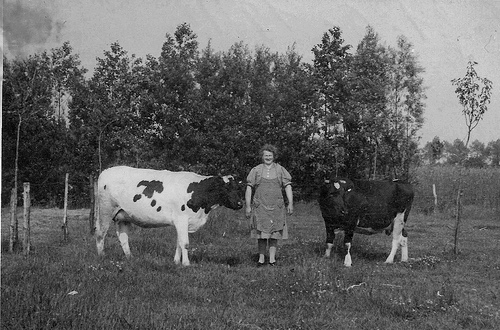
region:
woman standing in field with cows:
[241, 141, 303, 263]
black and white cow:
[87, 163, 242, 270]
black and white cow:
[308, 176, 413, 271]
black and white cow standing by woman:
[323, 176, 415, 268]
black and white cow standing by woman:
[91, 167, 246, 268]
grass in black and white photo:
[14, 261, 252, 328]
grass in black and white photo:
[272, 267, 496, 322]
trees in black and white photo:
[8, 50, 258, 157]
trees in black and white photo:
[200, 40, 414, 141]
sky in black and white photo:
[24, 2, 474, 24]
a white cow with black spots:
[78, 154, 244, 284]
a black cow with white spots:
[301, 176, 439, 273]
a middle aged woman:
[233, 126, 300, 282]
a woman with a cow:
[226, 143, 447, 291]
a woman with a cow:
[81, 133, 283, 269]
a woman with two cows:
[79, 148, 434, 289]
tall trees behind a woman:
[78, 25, 408, 187]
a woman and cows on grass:
[50, 110, 436, 308]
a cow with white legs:
[312, 170, 443, 270]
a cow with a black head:
[123, 160, 248, 321]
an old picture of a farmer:
[10, 6, 487, 321]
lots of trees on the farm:
[8, 15, 487, 235]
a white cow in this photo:
[78, 148, 246, 267]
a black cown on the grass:
[320, 157, 440, 274]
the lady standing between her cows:
[86, 122, 446, 279]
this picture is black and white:
[7, 23, 476, 283]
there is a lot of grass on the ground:
[23, 210, 488, 319]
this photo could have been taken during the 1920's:
[61, 92, 479, 271]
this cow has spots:
[115, 166, 243, 258]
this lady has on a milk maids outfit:
[76, 127, 296, 288]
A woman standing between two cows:
[74, 121, 430, 291]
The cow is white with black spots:
[83, 148, 248, 272]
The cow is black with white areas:
[308, 156, 453, 304]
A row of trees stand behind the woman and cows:
[6, 37, 435, 256]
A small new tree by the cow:
[431, 51, 498, 266]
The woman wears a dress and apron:
[246, 139, 306, 266]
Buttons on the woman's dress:
[266, 166, 272, 178]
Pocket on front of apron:
[271, 190, 288, 212]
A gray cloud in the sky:
[3, 4, 68, 63]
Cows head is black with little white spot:
[313, 166, 364, 231]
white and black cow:
[88, 164, 248, 274]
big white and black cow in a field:
[85, 160, 252, 261]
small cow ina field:
[315, 164, 410, 274]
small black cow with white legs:
[315, 165, 417, 269]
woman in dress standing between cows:
[244, 141, 295, 268]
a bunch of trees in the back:
[7, 24, 439, 205]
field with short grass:
[0, 158, 494, 326]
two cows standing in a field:
[88, 162, 413, 274]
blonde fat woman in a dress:
[242, 145, 299, 269]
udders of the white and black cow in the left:
[108, 202, 139, 233]